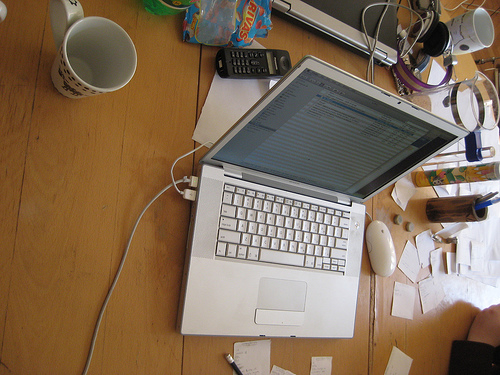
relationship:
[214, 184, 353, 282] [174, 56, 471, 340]
keyboard on laptop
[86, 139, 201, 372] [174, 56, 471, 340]
cords attached to laptop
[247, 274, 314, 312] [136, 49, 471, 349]
trackpad on laptop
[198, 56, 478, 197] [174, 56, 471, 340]
screen on laptop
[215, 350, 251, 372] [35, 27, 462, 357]
pencil on desk